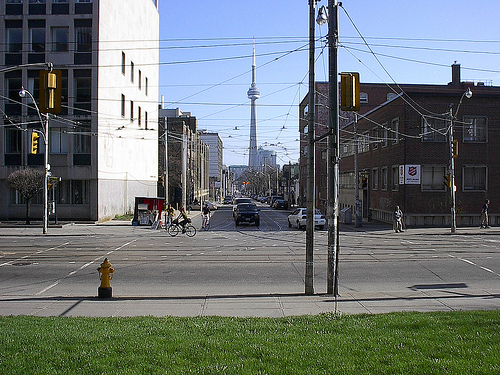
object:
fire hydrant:
[95, 257, 115, 304]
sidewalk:
[0, 288, 500, 315]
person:
[175, 206, 192, 234]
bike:
[168, 216, 198, 237]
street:
[0, 235, 499, 291]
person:
[393, 205, 404, 232]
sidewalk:
[375, 215, 500, 233]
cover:
[31, 130, 39, 155]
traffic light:
[33, 135, 41, 141]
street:
[215, 192, 300, 228]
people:
[249, 205, 254, 208]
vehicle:
[233, 203, 260, 226]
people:
[201, 205, 212, 228]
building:
[247, 36, 261, 166]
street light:
[341, 71, 360, 110]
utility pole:
[324, 4, 340, 299]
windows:
[52, 27, 68, 51]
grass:
[1, 314, 498, 374]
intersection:
[75, 213, 437, 316]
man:
[479, 199, 491, 229]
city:
[0, 2, 500, 373]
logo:
[407, 165, 420, 184]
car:
[286, 207, 328, 230]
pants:
[480, 210, 489, 227]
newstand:
[133, 196, 165, 225]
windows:
[121, 52, 126, 75]